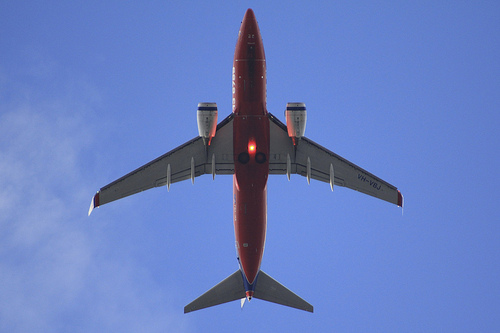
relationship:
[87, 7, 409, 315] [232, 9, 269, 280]
plane has body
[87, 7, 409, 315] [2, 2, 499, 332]
plane in sky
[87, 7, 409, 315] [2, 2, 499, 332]
plane up in sky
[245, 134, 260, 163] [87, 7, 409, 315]
light on bottom of plane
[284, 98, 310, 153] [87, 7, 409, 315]
engine on side of plane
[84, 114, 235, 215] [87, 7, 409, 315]
wing on side of plane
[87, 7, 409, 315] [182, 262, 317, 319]
plane has tail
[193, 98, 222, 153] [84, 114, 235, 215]
engine on bottom of wing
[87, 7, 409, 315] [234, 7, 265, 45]
plane has nose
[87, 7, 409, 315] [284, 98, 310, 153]
plane has engine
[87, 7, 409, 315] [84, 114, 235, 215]
plane has wing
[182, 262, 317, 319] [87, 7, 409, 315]
tail on end of plane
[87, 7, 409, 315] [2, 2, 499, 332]
plane soaring in sky